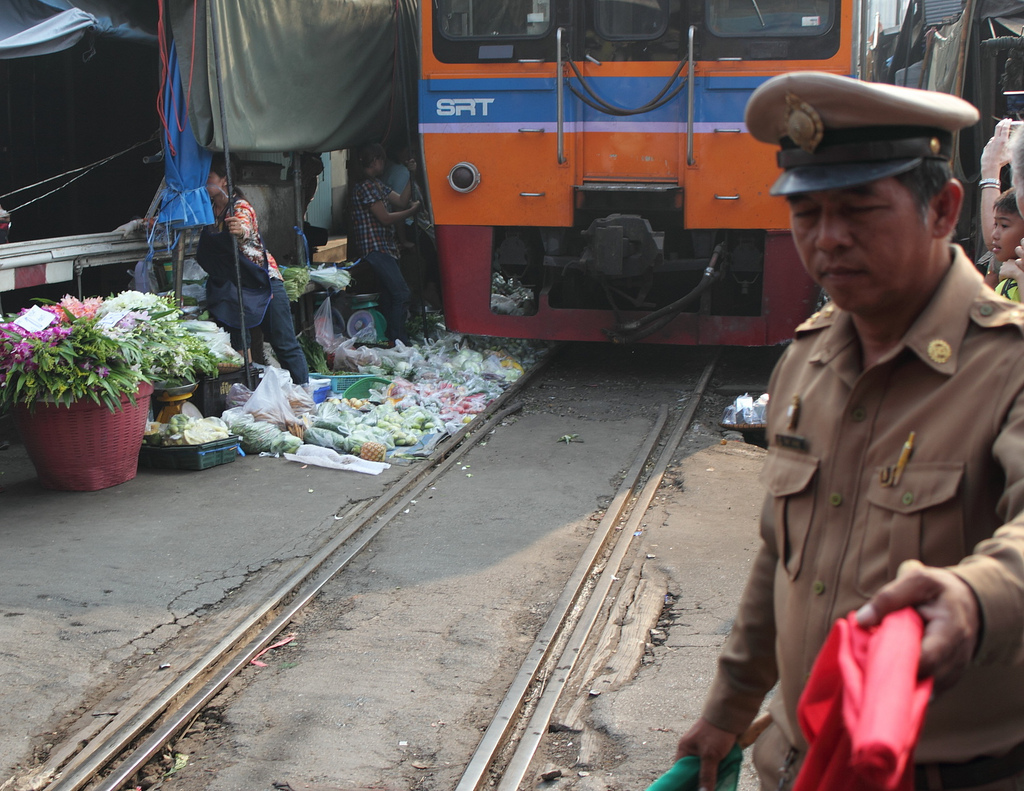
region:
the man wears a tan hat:
[733, 67, 983, 208]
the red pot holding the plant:
[5, 380, 168, 486]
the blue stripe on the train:
[412, 74, 789, 117]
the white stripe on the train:
[415, 118, 751, 134]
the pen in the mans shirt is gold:
[892, 425, 919, 479]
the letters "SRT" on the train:
[431, 90, 498, 123]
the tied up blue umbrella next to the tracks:
[149, 41, 220, 316]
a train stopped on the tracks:
[412, 0, 885, 373]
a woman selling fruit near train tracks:
[237, 309, 544, 474]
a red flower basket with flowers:
[6, 286, 162, 490]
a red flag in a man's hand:
[795, 587, 933, 787]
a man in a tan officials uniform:
[669, 65, 1021, 787]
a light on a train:
[445, 162, 477, 192]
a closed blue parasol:
[154, 14, 209, 305]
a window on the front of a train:
[431, 0, 555, 36]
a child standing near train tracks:
[989, 194, 1021, 293]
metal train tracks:
[63, 347, 732, 787]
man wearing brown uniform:
[695, 55, 1022, 784]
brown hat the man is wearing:
[736, 60, 996, 213]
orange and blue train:
[416, 6, 860, 232]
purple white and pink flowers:
[3, 284, 232, 409]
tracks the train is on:
[34, 357, 736, 788]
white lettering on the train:
[427, 92, 494, 131]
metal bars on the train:
[549, 23, 702, 166]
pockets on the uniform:
[756, 450, 962, 609]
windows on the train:
[439, 3, 841, 68]